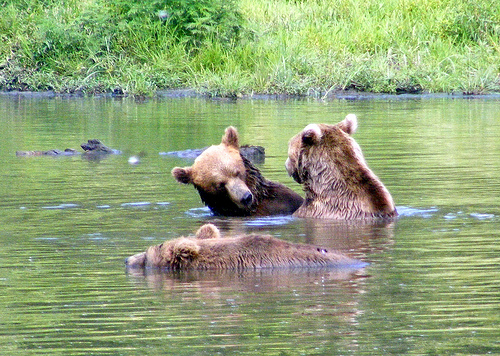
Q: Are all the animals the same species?
A: Yes, all the animals are bears.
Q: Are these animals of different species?
A: No, all the animals are bears.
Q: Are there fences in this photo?
A: No, there are no fences.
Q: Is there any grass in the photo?
A: Yes, there is grass.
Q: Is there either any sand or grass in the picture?
A: Yes, there is grass.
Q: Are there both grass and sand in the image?
A: No, there is grass but no sand.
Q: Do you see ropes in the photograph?
A: No, there are no ropes.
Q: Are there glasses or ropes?
A: No, there are no ropes or glasses.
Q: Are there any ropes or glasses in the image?
A: No, there are no ropes or glasses.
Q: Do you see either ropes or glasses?
A: No, there are no ropes or glasses.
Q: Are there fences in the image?
A: No, there are no fences.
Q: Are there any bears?
A: Yes, there is a bear.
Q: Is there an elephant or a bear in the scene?
A: Yes, there is a bear.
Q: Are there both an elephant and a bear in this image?
A: No, there is a bear but no elephants.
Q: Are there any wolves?
A: No, there are no wolves.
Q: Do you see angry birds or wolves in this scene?
A: No, there are no wolves or angry birds.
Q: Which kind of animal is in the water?
A: The animal is a bear.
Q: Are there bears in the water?
A: Yes, there is a bear in the water.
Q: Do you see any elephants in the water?
A: No, there is a bear in the water.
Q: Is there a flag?
A: No, there are no flags.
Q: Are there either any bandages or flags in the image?
A: No, there are no flags or bandages.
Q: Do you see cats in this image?
A: No, there are no cats.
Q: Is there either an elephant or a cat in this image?
A: No, there are no cats or elephants.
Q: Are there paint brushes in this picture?
A: No, there are no paint brushes.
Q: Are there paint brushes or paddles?
A: No, there are no paint brushes or paddles.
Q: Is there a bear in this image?
A: Yes, there is a bear.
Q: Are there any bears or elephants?
A: Yes, there is a bear.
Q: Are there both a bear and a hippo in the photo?
A: No, there is a bear but no hippos.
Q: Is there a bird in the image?
A: No, there are no birds.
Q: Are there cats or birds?
A: No, there are no birds or cats.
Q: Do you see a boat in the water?
A: No, there is a bear in the water.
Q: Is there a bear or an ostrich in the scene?
A: Yes, there is a bear.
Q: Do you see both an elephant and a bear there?
A: No, there is a bear but no elephants.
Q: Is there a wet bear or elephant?
A: Yes, there is a wet bear.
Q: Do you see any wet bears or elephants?
A: Yes, there is a wet bear.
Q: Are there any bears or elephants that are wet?
A: Yes, the bear is wet.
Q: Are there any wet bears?
A: Yes, there is a wet bear.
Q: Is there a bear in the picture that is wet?
A: Yes, there is a bear that is wet.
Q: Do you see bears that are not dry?
A: Yes, there is a wet bear.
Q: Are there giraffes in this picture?
A: No, there are no giraffes.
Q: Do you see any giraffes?
A: No, there are no giraffes.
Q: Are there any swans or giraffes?
A: No, there are no giraffes or swans.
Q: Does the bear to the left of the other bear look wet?
A: Yes, the bear is wet.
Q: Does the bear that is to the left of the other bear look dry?
A: No, the bear is wet.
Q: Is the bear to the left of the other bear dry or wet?
A: The bear is wet.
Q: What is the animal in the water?
A: The animal is a bear.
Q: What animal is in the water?
A: The animal is a bear.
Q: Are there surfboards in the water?
A: No, there is a bear in the water.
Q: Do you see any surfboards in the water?
A: No, there is a bear in the water.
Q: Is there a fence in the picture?
A: No, there are no fences.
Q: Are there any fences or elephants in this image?
A: No, there are no fences or elephants.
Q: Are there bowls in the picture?
A: No, there are no bowls.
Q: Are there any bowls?
A: No, there are no bowls.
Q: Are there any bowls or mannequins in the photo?
A: No, there are no bowls or mannequins.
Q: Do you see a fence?
A: No, there are no fences.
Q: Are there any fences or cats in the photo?
A: No, there are no fences or cats.